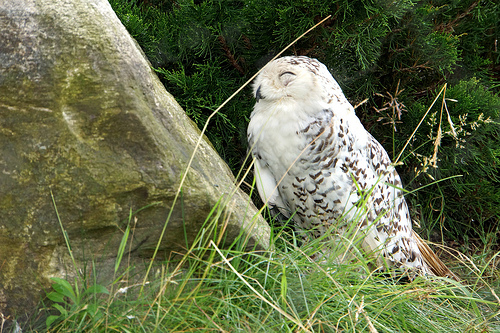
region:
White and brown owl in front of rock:
[239, 55, 441, 278]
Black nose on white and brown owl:
[254, 84, 266, 104]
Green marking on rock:
[0, 20, 209, 295]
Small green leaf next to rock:
[48, 272, 73, 304]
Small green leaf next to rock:
[41, 289, 72, 305]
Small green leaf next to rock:
[82, 283, 114, 300]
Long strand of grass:
[125, 11, 335, 306]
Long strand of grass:
[190, 92, 375, 297]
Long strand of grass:
[172, 114, 279, 301]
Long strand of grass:
[230, 189, 311, 311]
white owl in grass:
[252, 62, 448, 286]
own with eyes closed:
[228, 63, 453, 283]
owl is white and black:
[230, 63, 447, 283]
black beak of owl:
[255, 86, 265, 102]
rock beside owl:
[0, 0, 255, 312]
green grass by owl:
[44, 219, 497, 327]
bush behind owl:
[127, 8, 494, 238]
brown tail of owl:
[409, 235, 460, 282]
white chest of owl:
[240, 117, 312, 167]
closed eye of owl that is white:
[277, 66, 297, 78]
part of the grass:
[386, 242, 414, 289]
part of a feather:
[313, 155, 328, 196]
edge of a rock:
[108, 40, 168, 148]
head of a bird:
[286, 68, 296, 91]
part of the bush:
[190, 13, 215, 87]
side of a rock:
[132, 98, 152, 131]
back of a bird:
[325, 76, 342, 156]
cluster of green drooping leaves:
[43, 273, 105, 331]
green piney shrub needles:
[158, 8, 215, 68]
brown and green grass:
[256, 283, 353, 330]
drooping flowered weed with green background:
[422, 80, 482, 169]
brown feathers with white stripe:
[420, 238, 447, 275]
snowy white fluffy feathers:
[256, 120, 298, 152]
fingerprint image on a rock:
[56, 58, 118, 142]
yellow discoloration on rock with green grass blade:
[3, 168, 106, 234]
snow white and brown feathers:
[313, 155, 364, 196]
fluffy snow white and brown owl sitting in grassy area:
[243, 56, 455, 282]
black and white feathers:
[289, 174, 344, 213]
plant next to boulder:
[44, 268, 100, 332]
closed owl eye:
[273, 67, 302, 89]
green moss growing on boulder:
[51, 75, 137, 181]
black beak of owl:
[248, 82, 275, 106]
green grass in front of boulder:
[203, 252, 228, 332]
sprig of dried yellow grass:
[430, 88, 488, 176]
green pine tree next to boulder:
[157, 11, 247, 175]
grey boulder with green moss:
[1, 5, 251, 331]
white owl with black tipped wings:
[225, 40, 448, 301]